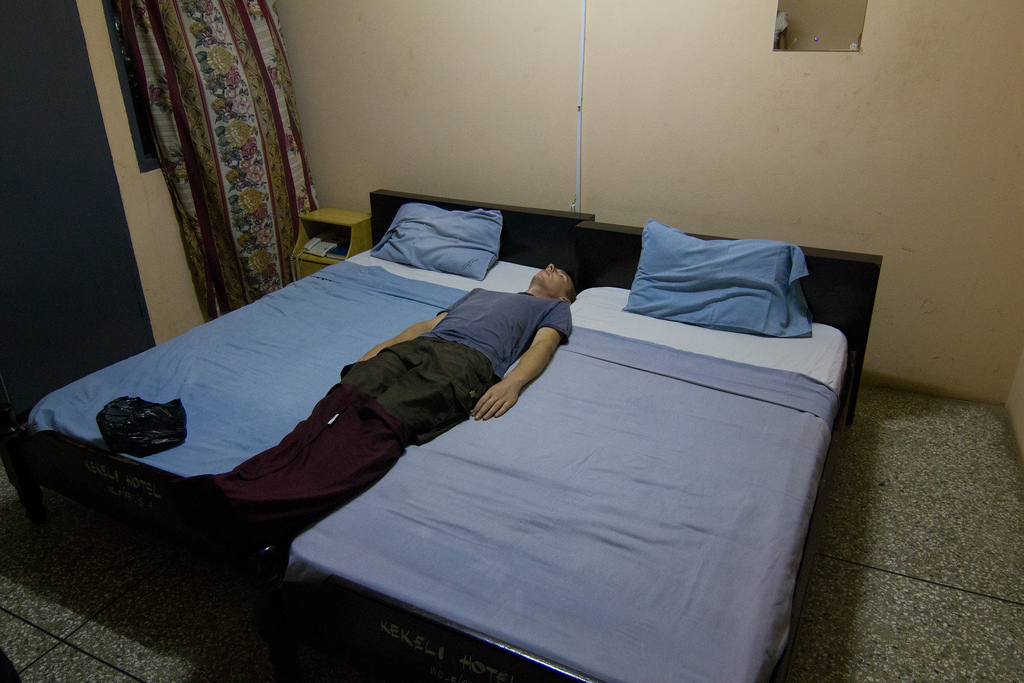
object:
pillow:
[370, 202, 503, 280]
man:
[183, 263, 576, 542]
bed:
[0, 189, 883, 683]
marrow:
[773, 1, 868, 53]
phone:
[290, 231, 345, 282]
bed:
[0, 189, 596, 565]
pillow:
[622, 217, 813, 337]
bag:
[96, 395, 187, 458]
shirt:
[421, 288, 572, 381]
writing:
[86, 460, 162, 507]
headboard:
[0, 403, 260, 569]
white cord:
[574, 0, 586, 213]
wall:
[268, 0, 1020, 404]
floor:
[0, 384, 1021, 682]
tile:
[819, 381, 1023, 604]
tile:
[787, 551, 1024, 683]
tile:
[62, 541, 362, 683]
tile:
[0, 457, 206, 639]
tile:
[17, 642, 139, 683]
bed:
[259, 221, 882, 683]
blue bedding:
[283, 326, 839, 683]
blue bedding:
[28, 261, 471, 478]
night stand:
[290, 207, 373, 282]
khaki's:
[340, 336, 502, 446]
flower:
[207, 45, 234, 74]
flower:
[241, 137, 257, 156]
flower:
[237, 188, 263, 214]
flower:
[253, 203, 269, 221]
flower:
[253, 224, 274, 245]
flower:
[231, 93, 252, 116]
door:
[0, 0, 155, 414]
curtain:
[118, 0, 322, 318]